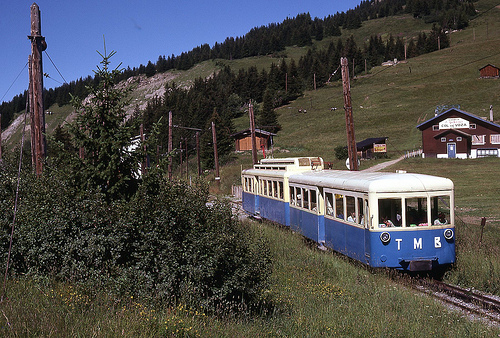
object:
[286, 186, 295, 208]
window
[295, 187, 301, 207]
window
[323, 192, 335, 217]
window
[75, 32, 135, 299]
trees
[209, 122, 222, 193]
post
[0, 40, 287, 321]
bushes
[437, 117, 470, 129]
banner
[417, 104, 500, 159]
building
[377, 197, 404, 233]
window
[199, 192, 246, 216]
tracks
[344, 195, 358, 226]
window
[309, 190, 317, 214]
window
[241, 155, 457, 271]
train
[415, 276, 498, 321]
track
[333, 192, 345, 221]
window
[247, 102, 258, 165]
pole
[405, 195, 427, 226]
window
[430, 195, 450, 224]
window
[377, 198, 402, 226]
window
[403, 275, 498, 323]
tracks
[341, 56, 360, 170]
pole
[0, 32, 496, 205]
hill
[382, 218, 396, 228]
people